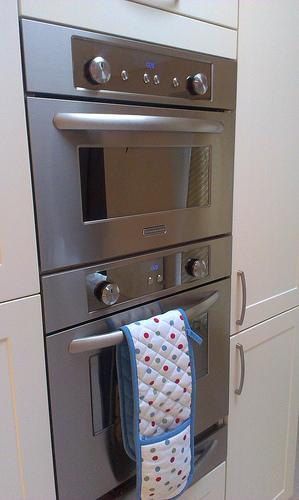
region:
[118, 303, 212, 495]
the oven holder has polka dots on it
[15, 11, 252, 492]
stoves stacked on top of each other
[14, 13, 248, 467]
stoves are silver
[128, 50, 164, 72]
the stove has a digital display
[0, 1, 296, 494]
stoves are built into cabinet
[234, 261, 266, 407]
handles on cabinet are silver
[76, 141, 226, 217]
window on stove is black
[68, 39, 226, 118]
knobs on stove are silver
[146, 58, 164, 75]
digital display is blue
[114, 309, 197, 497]
oven handler is on bottom stove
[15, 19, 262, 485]
two ovens on top of each other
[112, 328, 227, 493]
a oven mit hanging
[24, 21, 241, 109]
the handles on the oven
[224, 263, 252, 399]
the two handles to to the cupboard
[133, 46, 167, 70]
the time on the oven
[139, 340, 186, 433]
polka dots on the mit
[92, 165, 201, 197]
the window on the oven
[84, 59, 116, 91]
the dial on the oven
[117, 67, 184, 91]
four buttons on the oven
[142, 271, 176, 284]
the bottom ovens buttons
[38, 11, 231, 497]
a pair of ovens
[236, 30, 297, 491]
A cabinet door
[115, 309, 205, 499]
a colorful oven towel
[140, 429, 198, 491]
A pocket on the oven towel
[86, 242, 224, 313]
A digital display on the oven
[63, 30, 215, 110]
A digital display on the oven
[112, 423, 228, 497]
a drawer under the oven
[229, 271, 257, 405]
handles to the cabinet door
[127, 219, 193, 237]
The branding on the oven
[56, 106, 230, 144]
The handle of an oven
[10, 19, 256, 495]
silver oven on top of another silver oven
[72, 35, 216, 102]
panel of shiny knobs and buttons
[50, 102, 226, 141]
curved metal handle on top of door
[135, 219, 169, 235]
metal plate showing manufacturer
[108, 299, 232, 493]
connected oven mitts covered in dots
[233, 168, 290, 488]
silver handles on white cabinets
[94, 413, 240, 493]
narrow metal drawer below oven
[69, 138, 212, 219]
window reflection showing solid and stripes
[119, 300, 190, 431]
quilted squares on oven mitts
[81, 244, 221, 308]
two silver buttons between two knobs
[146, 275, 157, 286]
a nob on the cooker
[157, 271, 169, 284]
a nob on the cooker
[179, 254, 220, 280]
a nob on the cooker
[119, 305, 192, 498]
a blue and red doted holder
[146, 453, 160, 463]
a red dot partten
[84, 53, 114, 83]
a nob on the cooker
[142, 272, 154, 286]
a nob on the cooker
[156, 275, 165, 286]
a nob on the cooker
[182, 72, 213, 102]
a nob on the cooker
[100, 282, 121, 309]
a nob on the cooker